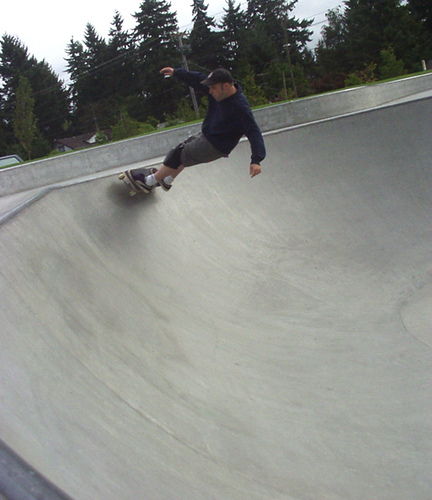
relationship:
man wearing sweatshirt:
[132, 59, 276, 204] [196, 98, 254, 160]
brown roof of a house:
[55, 127, 111, 150] [45, 127, 112, 156]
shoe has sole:
[129, 172, 151, 194] [149, 170, 165, 191]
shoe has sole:
[152, 167, 174, 191] [128, 171, 148, 193]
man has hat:
[124, 68, 266, 194] [197, 67, 232, 89]